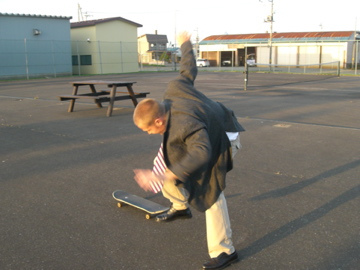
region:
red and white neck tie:
[151, 143, 167, 195]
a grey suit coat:
[164, 41, 245, 215]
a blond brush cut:
[131, 93, 167, 126]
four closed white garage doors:
[253, 44, 353, 76]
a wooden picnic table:
[61, 68, 146, 115]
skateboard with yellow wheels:
[108, 186, 168, 220]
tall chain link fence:
[1, 37, 178, 78]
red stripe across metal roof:
[201, 24, 357, 46]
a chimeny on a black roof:
[147, 23, 162, 40]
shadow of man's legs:
[240, 159, 358, 264]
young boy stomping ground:
[132, 31, 248, 269]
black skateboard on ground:
[112, 188, 168, 216]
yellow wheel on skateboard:
[117, 201, 121, 206]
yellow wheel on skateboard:
[145, 213, 149, 218]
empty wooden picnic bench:
[58, 79, 150, 117]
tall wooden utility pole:
[263, 0, 273, 68]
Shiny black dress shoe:
[199, 250, 237, 269]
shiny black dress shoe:
[156, 206, 192, 221]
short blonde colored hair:
[133, 99, 164, 125]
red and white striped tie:
[151, 143, 165, 193]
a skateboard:
[112, 185, 163, 223]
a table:
[72, 83, 120, 111]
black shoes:
[208, 256, 239, 269]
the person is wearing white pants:
[202, 208, 238, 254]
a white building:
[90, 22, 140, 66]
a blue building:
[2, 18, 72, 75]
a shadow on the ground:
[256, 179, 312, 231]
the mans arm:
[176, 38, 194, 74]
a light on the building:
[32, 26, 39, 33]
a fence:
[284, 62, 341, 72]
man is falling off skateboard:
[115, 52, 296, 267]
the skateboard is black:
[103, 163, 190, 232]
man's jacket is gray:
[154, 59, 273, 229]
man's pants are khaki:
[188, 159, 253, 249]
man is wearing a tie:
[143, 149, 174, 192]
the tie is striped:
[140, 139, 180, 191]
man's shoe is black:
[189, 201, 238, 266]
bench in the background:
[55, 41, 146, 129]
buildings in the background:
[4, 2, 358, 98]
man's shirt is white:
[218, 122, 246, 150]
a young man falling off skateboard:
[113, 32, 242, 269]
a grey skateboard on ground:
[107, 188, 166, 222]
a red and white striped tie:
[148, 143, 166, 196]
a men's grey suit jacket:
[162, 41, 243, 209]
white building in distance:
[198, 32, 358, 66]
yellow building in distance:
[72, 14, 140, 77]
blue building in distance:
[0, 13, 72, 76]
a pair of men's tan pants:
[169, 136, 237, 256]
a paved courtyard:
[0, 72, 358, 269]